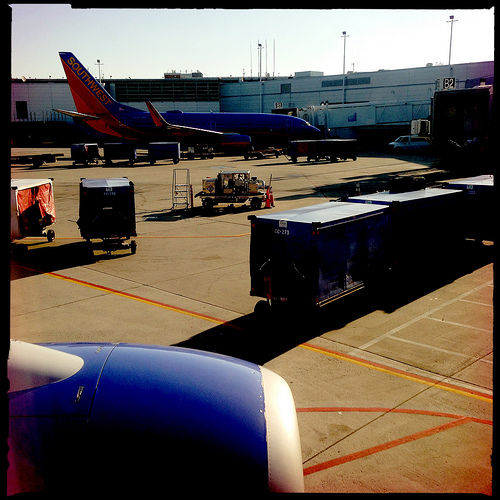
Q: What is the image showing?
A: It is showing an airport.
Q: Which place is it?
A: It is an airport.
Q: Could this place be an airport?
A: Yes, it is an airport.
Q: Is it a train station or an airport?
A: It is an airport.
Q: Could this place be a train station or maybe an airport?
A: It is an airport.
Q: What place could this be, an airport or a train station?
A: It is an airport.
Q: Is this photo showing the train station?
A: No, the picture is showing the airport.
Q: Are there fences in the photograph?
A: No, there are no fences.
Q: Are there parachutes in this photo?
A: No, there are no parachutes.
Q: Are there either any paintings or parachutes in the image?
A: No, there are no parachutes or paintings.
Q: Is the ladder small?
A: Yes, the ladder is small.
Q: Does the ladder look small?
A: Yes, the ladder is small.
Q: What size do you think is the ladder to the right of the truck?
A: The ladder is small.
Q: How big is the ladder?
A: The ladder is small.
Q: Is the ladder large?
A: No, the ladder is small.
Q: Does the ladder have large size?
A: No, the ladder is small.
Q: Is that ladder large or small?
A: The ladder is small.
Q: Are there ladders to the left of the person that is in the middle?
A: Yes, there is a ladder to the left of the person.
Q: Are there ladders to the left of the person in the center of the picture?
A: Yes, there is a ladder to the left of the person.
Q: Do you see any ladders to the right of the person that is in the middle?
A: No, the ladder is to the left of the person.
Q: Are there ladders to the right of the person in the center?
A: No, the ladder is to the left of the person.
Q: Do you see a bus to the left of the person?
A: No, there is a ladder to the left of the person.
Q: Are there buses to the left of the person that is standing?
A: No, there is a ladder to the left of the person.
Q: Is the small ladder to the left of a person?
A: Yes, the ladder is to the left of a person.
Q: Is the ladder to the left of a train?
A: No, the ladder is to the left of a person.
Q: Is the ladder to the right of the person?
A: No, the ladder is to the left of the person.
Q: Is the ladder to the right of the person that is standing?
A: No, the ladder is to the left of the person.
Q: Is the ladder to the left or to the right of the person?
A: The ladder is to the left of the person.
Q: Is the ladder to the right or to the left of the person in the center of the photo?
A: The ladder is to the left of the person.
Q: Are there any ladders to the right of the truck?
A: Yes, there is a ladder to the right of the truck.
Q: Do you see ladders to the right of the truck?
A: Yes, there is a ladder to the right of the truck.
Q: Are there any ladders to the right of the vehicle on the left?
A: Yes, there is a ladder to the right of the truck.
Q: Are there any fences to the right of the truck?
A: No, there is a ladder to the right of the truck.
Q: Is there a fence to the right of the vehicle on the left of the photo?
A: No, there is a ladder to the right of the truck.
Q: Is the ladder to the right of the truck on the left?
A: Yes, the ladder is to the right of the truck.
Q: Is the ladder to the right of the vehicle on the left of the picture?
A: Yes, the ladder is to the right of the truck.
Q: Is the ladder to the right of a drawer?
A: No, the ladder is to the right of the truck.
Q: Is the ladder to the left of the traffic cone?
A: Yes, the ladder is to the left of the traffic cone.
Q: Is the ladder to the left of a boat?
A: No, the ladder is to the left of the traffic cone.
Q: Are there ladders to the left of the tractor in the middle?
A: Yes, there is a ladder to the left of the tractor.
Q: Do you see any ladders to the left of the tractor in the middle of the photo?
A: Yes, there is a ladder to the left of the tractor.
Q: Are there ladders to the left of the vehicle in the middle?
A: Yes, there is a ladder to the left of the tractor.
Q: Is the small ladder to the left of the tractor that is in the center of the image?
A: Yes, the ladder is to the left of the tractor.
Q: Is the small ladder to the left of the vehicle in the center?
A: Yes, the ladder is to the left of the tractor.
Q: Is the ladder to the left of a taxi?
A: No, the ladder is to the left of the tractor.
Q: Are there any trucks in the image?
A: Yes, there is a truck.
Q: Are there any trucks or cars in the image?
A: Yes, there is a truck.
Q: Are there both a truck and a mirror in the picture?
A: No, there is a truck but no mirrors.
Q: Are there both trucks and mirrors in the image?
A: No, there is a truck but no mirrors.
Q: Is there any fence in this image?
A: No, there are no fences.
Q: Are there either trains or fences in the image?
A: No, there are no fences or trains.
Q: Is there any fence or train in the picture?
A: No, there are no fences or trains.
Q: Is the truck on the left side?
A: Yes, the truck is on the left of the image.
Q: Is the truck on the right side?
A: No, the truck is on the left of the image.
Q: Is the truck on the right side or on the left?
A: The truck is on the left of the image.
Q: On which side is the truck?
A: The truck is on the left of the image.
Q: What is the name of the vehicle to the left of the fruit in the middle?
A: The vehicle is a truck.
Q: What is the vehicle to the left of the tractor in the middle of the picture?
A: The vehicle is a truck.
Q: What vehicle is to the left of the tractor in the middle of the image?
A: The vehicle is a truck.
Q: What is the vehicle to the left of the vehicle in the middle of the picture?
A: The vehicle is a truck.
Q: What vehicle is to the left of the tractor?
A: The vehicle is a truck.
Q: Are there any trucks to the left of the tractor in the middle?
A: Yes, there is a truck to the left of the tractor.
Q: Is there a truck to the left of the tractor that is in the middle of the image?
A: Yes, there is a truck to the left of the tractor.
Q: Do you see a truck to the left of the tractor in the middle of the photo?
A: Yes, there is a truck to the left of the tractor.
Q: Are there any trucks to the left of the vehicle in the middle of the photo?
A: Yes, there is a truck to the left of the tractor.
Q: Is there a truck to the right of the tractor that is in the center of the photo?
A: No, the truck is to the left of the tractor.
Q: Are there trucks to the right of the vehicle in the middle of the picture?
A: No, the truck is to the left of the tractor.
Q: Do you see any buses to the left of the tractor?
A: No, there is a truck to the left of the tractor.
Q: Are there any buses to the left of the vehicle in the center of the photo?
A: No, there is a truck to the left of the tractor.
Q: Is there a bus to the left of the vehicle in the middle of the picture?
A: No, there is a truck to the left of the tractor.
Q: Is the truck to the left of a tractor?
A: Yes, the truck is to the left of a tractor.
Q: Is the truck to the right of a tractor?
A: No, the truck is to the left of a tractor.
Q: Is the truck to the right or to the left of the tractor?
A: The truck is to the left of the tractor.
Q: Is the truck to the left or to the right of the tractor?
A: The truck is to the left of the tractor.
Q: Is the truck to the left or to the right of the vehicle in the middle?
A: The truck is to the left of the tractor.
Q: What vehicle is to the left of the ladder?
A: The vehicle is a truck.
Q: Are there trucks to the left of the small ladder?
A: Yes, there is a truck to the left of the ladder.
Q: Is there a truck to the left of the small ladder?
A: Yes, there is a truck to the left of the ladder.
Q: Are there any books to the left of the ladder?
A: No, there is a truck to the left of the ladder.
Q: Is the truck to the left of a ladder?
A: Yes, the truck is to the left of a ladder.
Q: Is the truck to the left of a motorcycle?
A: No, the truck is to the left of a ladder.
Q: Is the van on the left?
A: No, the van is on the right of the image.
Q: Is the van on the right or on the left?
A: The van is on the right of the image.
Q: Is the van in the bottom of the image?
A: No, the van is in the top of the image.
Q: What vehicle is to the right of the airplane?
A: The vehicle is a van.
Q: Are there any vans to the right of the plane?
A: Yes, there is a van to the right of the plane.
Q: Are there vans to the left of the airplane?
A: No, the van is to the right of the airplane.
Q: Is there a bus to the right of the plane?
A: No, there is a van to the right of the plane.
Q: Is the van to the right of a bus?
A: No, the van is to the right of the plane.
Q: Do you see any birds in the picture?
A: No, there are no birds.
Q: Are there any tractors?
A: Yes, there is a tractor.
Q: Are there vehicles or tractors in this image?
A: Yes, there is a tractor.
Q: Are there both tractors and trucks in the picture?
A: Yes, there are both a tractor and a truck.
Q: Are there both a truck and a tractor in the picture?
A: Yes, there are both a tractor and a truck.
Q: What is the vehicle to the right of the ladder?
A: The vehicle is a tractor.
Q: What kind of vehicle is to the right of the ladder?
A: The vehicle is a tractor.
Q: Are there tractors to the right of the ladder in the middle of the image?
A: Yes, there is a tractor to the right of the ladder.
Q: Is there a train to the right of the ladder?
A: No, there is a tractor to the right of the ladder.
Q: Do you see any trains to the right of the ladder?
A: No, there is a tractor to the right of the ladder.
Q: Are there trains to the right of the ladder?
A: No, there is a tractor to the right of the ladder.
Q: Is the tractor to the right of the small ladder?
A: Yes, the tractor is to the right of the ladder.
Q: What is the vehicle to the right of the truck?
A: The vehicle is a tractor.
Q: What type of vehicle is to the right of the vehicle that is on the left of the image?
A: The vehicle is a tractor.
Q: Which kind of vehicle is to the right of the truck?
A: The vehicle is a tractor.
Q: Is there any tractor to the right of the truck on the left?
A: Yes, there is a tractor to the right of the truck.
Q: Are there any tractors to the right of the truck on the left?
A: Yes, there is a tractor to the right of the truck.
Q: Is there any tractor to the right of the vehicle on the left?
A: Yes, there is a tractor to the right of the truck.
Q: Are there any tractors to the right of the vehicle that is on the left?
A: Yes, there is a tractor to the right of the truck.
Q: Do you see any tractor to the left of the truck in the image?
A: No, the tractor is to the right of the truck.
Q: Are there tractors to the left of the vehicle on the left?
A: No, the tractor is to the right of the truck.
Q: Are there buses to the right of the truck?
A: No, there is a tractor to the right of the truck.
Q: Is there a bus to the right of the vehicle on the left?
A: No, there is a tractor to the right of the truck.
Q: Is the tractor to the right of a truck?
A: Yes, the tractor is to the right of a truck.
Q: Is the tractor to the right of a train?
A: No, the tractor is to the right of a truck.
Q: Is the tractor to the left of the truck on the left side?
A: No, the tractor is to the right of the truck.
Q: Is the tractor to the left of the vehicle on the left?
A: No, the tractor is to the right of the truck.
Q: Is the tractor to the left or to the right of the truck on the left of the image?
A: The tractor is to the right of the truck.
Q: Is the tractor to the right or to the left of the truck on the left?
A: The tractor is to the right of the truck.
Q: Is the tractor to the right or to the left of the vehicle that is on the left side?
A: The tractor is to the right of the truck.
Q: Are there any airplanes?
A: Yes, there is an airplane.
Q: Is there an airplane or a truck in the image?
A: Yes, there is an airplane.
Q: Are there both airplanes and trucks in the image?
A: Yes, there are both an airplane and a truck.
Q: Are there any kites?
A: No, there are no kites.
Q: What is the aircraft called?
A: The aircraft is an airplane.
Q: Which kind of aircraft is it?
A: The aircraft is an airplane.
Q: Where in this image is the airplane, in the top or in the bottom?
A: The airplane is in the top of the image.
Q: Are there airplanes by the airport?
A: Yes, there is an airplane by the airport.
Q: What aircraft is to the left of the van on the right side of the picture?
A: The aircraft is an airplane.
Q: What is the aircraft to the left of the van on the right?
A: The aircraft is an airplane.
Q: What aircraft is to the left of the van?
A: The aircraft is an airplane.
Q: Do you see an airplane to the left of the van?
A: Yes, there is an airplane to the left of the van.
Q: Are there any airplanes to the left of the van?
A: Yes, there is an airplane to the left of the van.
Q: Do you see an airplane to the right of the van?
A: No, the airplane is to the left of the van.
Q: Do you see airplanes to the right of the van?
A: No, the airplane is to the left of the van.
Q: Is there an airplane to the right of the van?
A: No, the airplane is to the left of the van.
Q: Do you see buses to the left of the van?
A: No, there is an airplane to the left of the van.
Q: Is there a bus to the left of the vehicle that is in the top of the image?
A: No, there is an airplane to the left of the van.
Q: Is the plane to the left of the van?
A: Yes, the plane is to the left of the van.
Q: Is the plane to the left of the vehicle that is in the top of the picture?
A: Yes, the plane is to the left of the van.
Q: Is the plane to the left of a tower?
A: No, the plane is to the left of the van.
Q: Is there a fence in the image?
A: No, there are no fences.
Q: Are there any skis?
A: No, there are no skis.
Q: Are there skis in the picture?
A: No, there are no skis.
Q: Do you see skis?
A: No, there are no skis.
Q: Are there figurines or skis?
A: No, there are no skis or figurines.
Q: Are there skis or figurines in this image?
A: No, there are no skis or figurines.